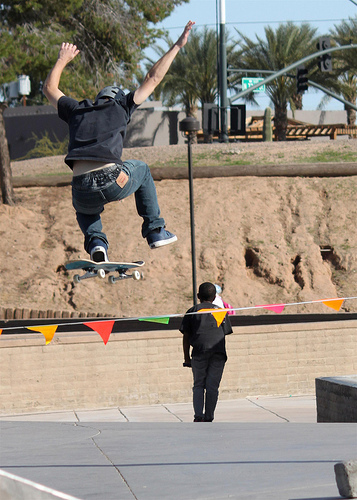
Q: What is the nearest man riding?
A: Skateboard.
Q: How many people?
A: Two.